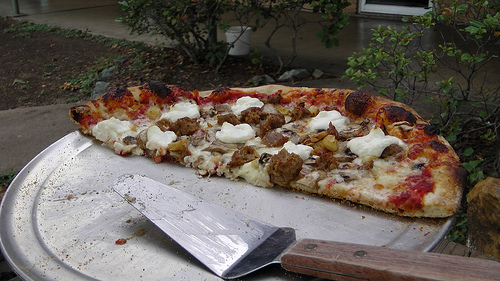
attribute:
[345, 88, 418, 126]
edge — burnt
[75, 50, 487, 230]
pizza — cooked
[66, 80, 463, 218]
pizza — half, cooked, baked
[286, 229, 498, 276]
handle — wood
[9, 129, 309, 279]
silver tray — round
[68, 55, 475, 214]
half pizza — cooked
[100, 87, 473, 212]
pizza — baked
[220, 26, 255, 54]
bucket — white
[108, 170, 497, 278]
spatula — metal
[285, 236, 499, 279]
handle — wood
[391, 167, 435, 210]
sauce — red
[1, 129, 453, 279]
pan — silver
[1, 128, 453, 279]
tray — pizza